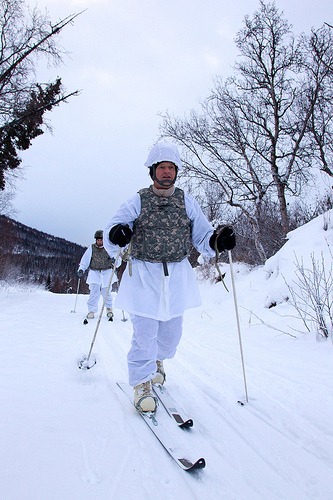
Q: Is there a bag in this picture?
A: No, there are no bags.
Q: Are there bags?
A: No, there are no bags.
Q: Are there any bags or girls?
A: No, there are no bags or girls.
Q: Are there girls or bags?
A: No, there are no bags or girls.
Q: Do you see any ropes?
A: No, there are no ropes.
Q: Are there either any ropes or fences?
A: No, there are no ropes or fences.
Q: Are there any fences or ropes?
A: No, there are no ropes or fences.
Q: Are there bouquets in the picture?
A: No, there are no bouquets.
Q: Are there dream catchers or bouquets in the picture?
A: No, there are no bouquets or dream catchers.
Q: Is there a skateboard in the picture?
A: No, there are no skateboards.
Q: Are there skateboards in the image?
A: No, there are no skateboards.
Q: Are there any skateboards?
A: No, there are no skateboards.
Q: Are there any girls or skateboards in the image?
A: No, there are no skateboards or girls.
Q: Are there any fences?
A: No, there are no fences.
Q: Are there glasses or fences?
A: No, there are no fences or glasses.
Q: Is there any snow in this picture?
A: Yes, there is snow.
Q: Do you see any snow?
A: Yes, there is snow.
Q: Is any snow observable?
A: Yes, there is snow.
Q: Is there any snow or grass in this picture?
A: Yes, there is snow.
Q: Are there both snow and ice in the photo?
A: No, there is snow but no ice.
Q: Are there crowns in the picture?
A: No, there are no crowns.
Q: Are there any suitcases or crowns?
A: No, there are no crowns or suitcases.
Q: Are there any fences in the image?
A: No, there are no fences.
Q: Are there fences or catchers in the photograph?
A: No, there are no fences or catchers.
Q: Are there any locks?
A: No, there are no locks.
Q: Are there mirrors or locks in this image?
A: No, there are no locks or mirrors.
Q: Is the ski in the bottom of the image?
A: Yes, the ski is in the bottom of the image.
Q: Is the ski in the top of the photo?
A: No, the ski is in the bottom of the image.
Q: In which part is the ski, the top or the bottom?
A: The ski is in the bottom of the image.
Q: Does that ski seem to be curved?
A: Yes, the ski is curved.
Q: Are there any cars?
A: No, there are no cars.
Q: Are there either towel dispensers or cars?
A: No, there are no cars or towel dispensers.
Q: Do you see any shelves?
A: No, there are no shelves.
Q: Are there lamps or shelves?
A: No, there are no shelves or lamps.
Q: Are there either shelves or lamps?
A: No, there are no shelves or lamps.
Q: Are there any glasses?
A: No, there are no glasses.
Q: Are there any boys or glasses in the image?
A: No, there are no glasses or boys.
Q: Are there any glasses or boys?
A: No, there are no glasses or boys.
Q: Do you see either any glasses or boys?
A: No, there are no glasses or boys.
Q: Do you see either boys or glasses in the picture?
A: No, there are no glasses or boys.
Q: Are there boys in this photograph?
A: No, there are no boys.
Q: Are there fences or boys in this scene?
A: No, there are no boys or fences.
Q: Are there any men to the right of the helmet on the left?
A: Yes, there is a man to the right of the helmet.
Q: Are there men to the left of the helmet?
A: No, the man is to the right of the helmet.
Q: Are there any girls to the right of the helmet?
A: No, there is a man to the right of the helmet.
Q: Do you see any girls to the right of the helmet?
A: No, there is a man to the right of the helmet.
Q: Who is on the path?
A: The man is on the path.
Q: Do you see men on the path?
A: Yes, there is a man on the path.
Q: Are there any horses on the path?
A: No, there is a man on the path.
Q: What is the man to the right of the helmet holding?
A: The man is holding the pole.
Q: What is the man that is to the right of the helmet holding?
A: The man is holding the pole.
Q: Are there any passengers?
A: No, there are no passengers.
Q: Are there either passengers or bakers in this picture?
A: No, there are no passengers or bakers.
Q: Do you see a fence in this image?
A: No, there are no fences.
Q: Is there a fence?
A: No, there are no fences.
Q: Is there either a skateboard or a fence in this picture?
A: No, there are no fences or skateboards.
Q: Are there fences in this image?
A: No, there are no fences.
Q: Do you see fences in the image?
A: No, there are no fences.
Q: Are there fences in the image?
A: No, there are no fences.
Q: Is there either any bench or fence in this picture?
A: No, there are no fences or benches.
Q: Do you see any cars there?
A: No, there are no cars.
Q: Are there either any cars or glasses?
A: No, there are no cars or glasses.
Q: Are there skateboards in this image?
A: No, there are no skateboards.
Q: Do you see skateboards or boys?
A: No, there are no skateboards or boys.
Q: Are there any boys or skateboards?
A: No, there are no skateboards or boys.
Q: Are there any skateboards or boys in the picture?
A: No, there are no skateboards or boys.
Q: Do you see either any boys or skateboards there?
A: No, there are no skateboards or boys.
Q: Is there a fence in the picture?
A: No, there are no fences.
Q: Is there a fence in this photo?
A: No, there are no fences.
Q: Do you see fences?
A: No, there are no fences.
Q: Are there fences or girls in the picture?
A: No, there are no fences or girls.